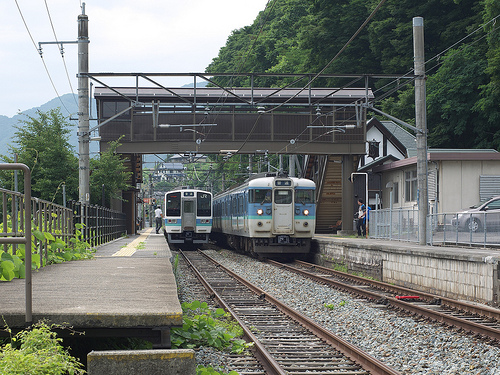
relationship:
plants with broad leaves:
[0, 210, 100, 282] [39, 224, 54, 242]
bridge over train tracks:
[93, 82, 373, 152] [180, 240, 498, 373]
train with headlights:
[218, 175, 318, 256] [258, 209, 310, 216]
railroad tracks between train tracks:
[248, 256, 499, 345] [180, 240, 498, 373]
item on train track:
[388, 281, 418, 319] [232, 257, 354, 360]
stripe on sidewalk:
[107, 223, 159, 267] [70, 210, 164, 340]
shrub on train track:
[186, 278, 243, 359] [175, 244, 412, 374]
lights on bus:
[238, 198, 319, 228] [186, 161, 313, 264]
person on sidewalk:
[152, 207, 160, 233] [104, 198, 195, 331]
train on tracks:
[212, 175, 318, 262] [228, 252, 404, 351]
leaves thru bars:
[48, 228, 75, 255] [11, 159, 60, 256]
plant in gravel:
[182, 286, 269, 350] [277, 273, 359, 317]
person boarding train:
[143, 199, 187, 246] [140, 150, 319, 241]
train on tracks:
[212, 175, 318, 262] [231, 241, 391, 353]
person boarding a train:
[152, 207, 160, 233] [151, 169, 228, 265]